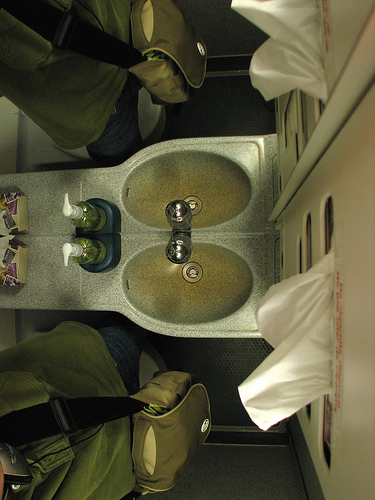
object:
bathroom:
[0, 0, 375, 500]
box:
[0, 240, 29, 286]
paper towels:
[1, 247, 16, 264]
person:
[0, 320, 167, 500]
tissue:
[238, 254, 335, 432]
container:
[268, 49, 374, 492]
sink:
[121, 242, 254, 325]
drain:
[183, 261, 203, 283]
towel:
[236, 251, 333, 431]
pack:
[132, 370, 211, 492]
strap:
[0, 396, 149, 446]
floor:
[162, 331, 301, 440]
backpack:
[0, 0, 206, 104]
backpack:
[0, 370, 212, 492]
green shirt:
[0, 0, 133, 151]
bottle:
[62, 238, 107, 266]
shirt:
[0, 321, 135, 499]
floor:
[157, 76, 275, 140]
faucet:
[165, 200, 193, 265]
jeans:
[86, 74, 141, 159]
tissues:
[240, 14, 328, 104]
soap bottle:
[62, 237, 106, 267]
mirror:
[0, 0, 374, 234]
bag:
[126, 0, 205, 105]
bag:
[131, 370, 212, 491]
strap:
[2, 0, 147, 69]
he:
[98, 326, 144, 396]